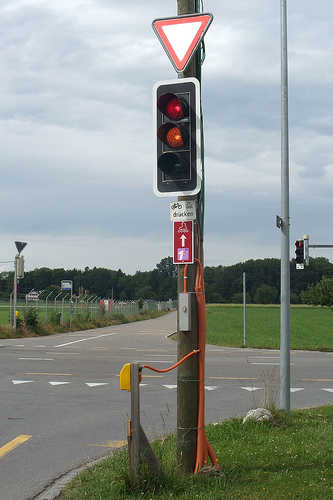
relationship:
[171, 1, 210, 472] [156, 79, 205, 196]
pole has signal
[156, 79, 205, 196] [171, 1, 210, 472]
signal on pole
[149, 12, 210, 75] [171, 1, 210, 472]
sign on pole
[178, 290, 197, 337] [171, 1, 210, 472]
box on pole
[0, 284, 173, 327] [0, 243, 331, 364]
fence in background